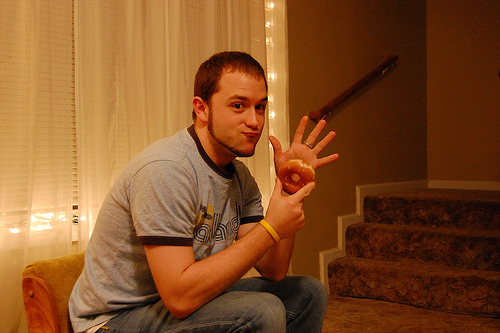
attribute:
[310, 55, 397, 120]
rail — wooden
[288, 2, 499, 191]
wall — brown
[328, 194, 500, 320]
stairs — brown, carpeted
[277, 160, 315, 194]
doughnut — glazed, whole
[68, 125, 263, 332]
shirt — blue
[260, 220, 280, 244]
bracelet — yellow, plastic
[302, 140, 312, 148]
ring — silver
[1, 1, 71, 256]
curtain — sheer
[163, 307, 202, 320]
right elbow — bent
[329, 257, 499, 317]
stair — carpeted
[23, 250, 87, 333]
chair — wooden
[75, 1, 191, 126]
curtain — white